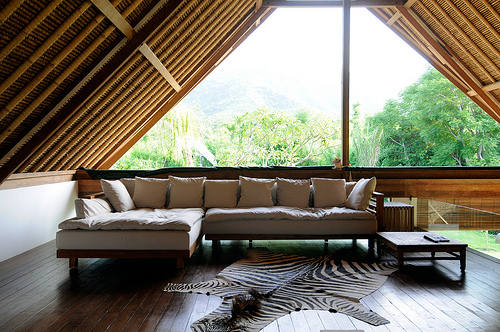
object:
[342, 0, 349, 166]
beam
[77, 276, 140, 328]
floor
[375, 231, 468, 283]
table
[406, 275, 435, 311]
ground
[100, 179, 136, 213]
pillow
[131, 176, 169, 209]
pillow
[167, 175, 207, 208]
pillow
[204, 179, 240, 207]
pillow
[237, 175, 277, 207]
pillow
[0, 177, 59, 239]
wall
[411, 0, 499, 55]
ceiling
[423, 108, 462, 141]
foliage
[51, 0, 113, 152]
door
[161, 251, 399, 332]
rug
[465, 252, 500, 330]
floor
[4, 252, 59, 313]
floor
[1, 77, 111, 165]
roof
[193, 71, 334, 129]
mountains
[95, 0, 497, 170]
window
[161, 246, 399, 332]
zebra's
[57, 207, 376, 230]
cushions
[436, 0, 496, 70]
roof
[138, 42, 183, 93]
beam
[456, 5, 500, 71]
beam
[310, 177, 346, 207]
pillow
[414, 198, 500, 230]
glass railing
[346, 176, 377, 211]
pillow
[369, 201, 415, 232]
table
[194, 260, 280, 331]
floor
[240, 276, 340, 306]
skin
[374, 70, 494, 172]
trees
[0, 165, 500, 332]
sitting area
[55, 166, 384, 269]
sofa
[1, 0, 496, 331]
room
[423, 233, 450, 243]
remotes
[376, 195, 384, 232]
handle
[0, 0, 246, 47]
roof